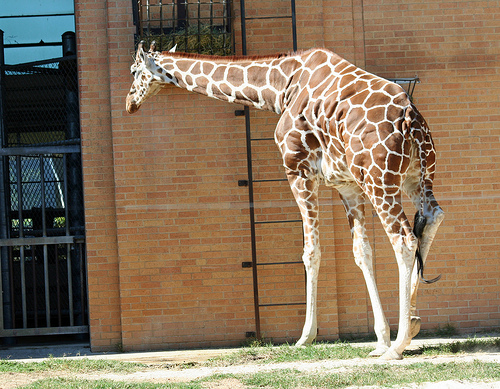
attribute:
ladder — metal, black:
[210, 0, 362, 335]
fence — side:
[3, 72, 91, 327]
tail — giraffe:
[398, 119, 433, 276]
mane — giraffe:
[158, 47, 307, 66]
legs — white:
[298, 205, 424, 352]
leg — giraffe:
[286, 170, 322, 343]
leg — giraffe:
[331, 184, 390, 357]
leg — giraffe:
[290, 175, 322, 349]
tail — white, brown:
[411, 128, 434, 280]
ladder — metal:
[238, 0, 318, 344]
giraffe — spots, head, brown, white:
[120, 35, 448, 364]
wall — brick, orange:
[72, 0, 498, 345]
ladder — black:
[229, 5, 329, 357]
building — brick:
[73, 18, 491, 328]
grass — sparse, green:
[0, 328, 498, 387]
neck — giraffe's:
[161, 51, 302, 115]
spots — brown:
[308, 73, 354, 127]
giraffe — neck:
[94, 28, 379, 208]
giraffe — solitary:
[197, 40, 487, 222]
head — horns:
[123, 36, 443, 360]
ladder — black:
[220, 173, 324, 262]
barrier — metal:
[8, 144, 86, 345]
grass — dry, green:
[273, 345, 343, 359]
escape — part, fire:
[234, 1, 324, 344]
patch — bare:
[255, 360, 346, 370]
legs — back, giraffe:
[373, 178, 446, 363]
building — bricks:
[76, 4, 484, 346]